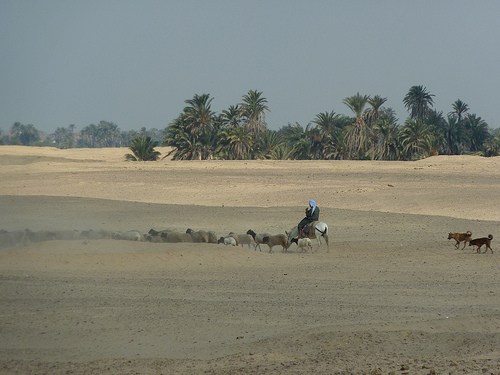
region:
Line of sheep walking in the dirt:
[25, 220, 306, 262]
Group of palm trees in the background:
[135, 85, 498, 175]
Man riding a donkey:
[280, 197, 344, 257]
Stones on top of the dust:
[156, 320, 473, 370]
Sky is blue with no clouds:
[69, 7, 196, 99]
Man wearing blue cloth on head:
[309, 196, 322, 215]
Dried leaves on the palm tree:
[340, 102, 378, 165]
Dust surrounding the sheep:
[12, 210, 178, 228]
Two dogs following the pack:
[437, 217, 498, 270]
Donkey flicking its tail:
[313, 222, 344, 246]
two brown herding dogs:
[442, 227, 499, 264]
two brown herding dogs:
[427, 201, 499, 288]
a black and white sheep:
[262, 229, 287, 254]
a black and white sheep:
[246, 226, 269, 248]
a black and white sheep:
[290, 237, 308, 249]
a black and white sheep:
[218, 235, 234, 247]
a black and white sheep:
[186, 227, 206, 243]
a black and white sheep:
[156, 229, 187, 241]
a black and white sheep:
[150, 227, 170, 242]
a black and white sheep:
[142, 233, 159, 243]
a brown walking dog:
[442, 230, 472, 249]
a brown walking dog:
[466, 234, 493, 254]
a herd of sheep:
[0, 225, 317, 252]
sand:
[4, 145, 497, 363]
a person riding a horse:
[296, 199, 333, 255]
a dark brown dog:
[469, 236, 497, 260]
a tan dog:
[444, 233, 474, 248]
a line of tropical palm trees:
[111, 90, 498, 179]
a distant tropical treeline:
[1, 122, 174, 149]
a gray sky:
[3, 0, 498, 117]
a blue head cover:
[306, 195, 320, 214]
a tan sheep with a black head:
[258, 232, 292, 250]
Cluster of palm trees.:
[168, 90, 485, 158]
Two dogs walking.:
[442, 222, 499, 256]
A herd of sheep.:
[1, 217, 288, 249]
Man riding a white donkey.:
[274, 197, 332, 246]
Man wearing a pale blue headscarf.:
[298, 196, 320, 231]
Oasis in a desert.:
[107, 70, 485, 197]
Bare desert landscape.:
[26, 258, 366, 341]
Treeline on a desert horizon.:
[0, 125, 162, 152]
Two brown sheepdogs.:
[439, 220, 495, 252]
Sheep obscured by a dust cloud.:
[0, 215, 125, 261]